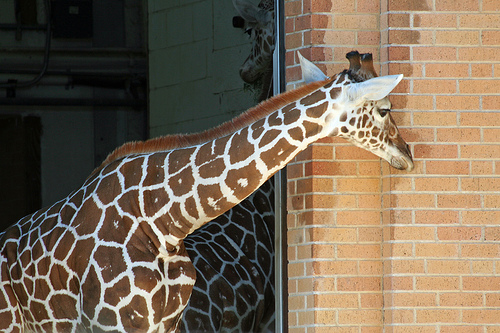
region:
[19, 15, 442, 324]
a giraffe near a building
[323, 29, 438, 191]
the giraffe looks liek he is kissing the building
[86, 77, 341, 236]
this animal has a long neck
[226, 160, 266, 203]
there are white spots in the brown patches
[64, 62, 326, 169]
a giraffe has short hair on its back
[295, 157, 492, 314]
a stone brick wall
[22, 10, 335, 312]
an open door way with giraffes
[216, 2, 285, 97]
this giraffe is in the background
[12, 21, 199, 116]
a wall in the building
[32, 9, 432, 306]
the giraffes are brown and white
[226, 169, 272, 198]
Brown and white spot on a giraffe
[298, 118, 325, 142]
Brown and white spot on a giraffe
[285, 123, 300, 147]
Brown and white spot on a giraffe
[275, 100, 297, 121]
Brown and white spot on a giraffe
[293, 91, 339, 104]
Brown and white spot on a giraffe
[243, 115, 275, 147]
Brown and white spot on a giraffe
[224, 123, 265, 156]
Brown and white spot on a giraffe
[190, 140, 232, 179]
Brown and white spot on a giraffe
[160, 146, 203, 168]
Brown and white spot on a giraffe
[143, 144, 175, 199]
Brown and white spot on a giraffe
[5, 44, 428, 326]
giraffe standing outside of brick building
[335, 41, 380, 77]
ossicones on top of giraffe head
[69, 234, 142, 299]
brown spots on giraffe fur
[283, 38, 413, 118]
two giraffe ears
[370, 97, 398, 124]
one giraffe ear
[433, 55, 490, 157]
red bricks on side of building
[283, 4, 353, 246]
red stain on wall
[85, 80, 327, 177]
brown giraffe mane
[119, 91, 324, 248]
long giraffe neck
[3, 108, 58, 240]
black doorway